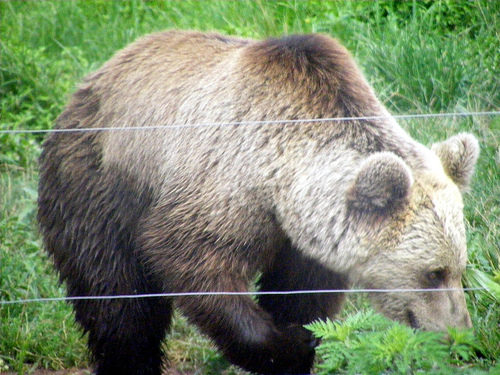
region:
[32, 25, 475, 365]
A bear held in captivity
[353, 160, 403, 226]
ear of the bear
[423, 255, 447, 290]
eye of the bear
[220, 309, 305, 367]
paw of the bear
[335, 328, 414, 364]
plants on the ground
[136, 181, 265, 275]
brown fur of bear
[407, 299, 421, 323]
mouth of the bear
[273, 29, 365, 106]
hump of the bear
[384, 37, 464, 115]
grass on the ground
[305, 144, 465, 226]
bear has brown ears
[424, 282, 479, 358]
bear has light brown nose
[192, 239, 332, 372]
bear has dark brown paws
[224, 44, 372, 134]
brown streak on back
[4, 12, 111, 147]
grass is bright green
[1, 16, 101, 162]
weedy grass behind bear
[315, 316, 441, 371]
leafy grass near bear's mouth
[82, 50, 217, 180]
light brown fur on bear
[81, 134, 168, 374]
bear's legs are dark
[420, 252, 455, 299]
bear has dark eyes